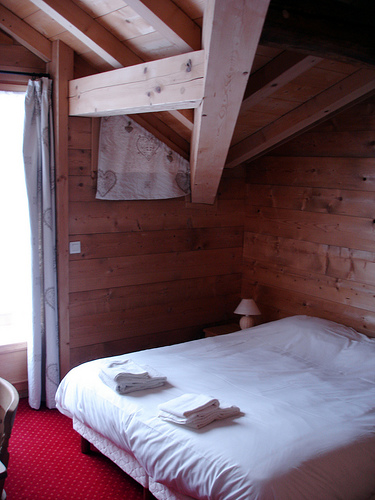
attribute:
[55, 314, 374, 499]
bed — white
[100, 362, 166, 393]
towels — white, piled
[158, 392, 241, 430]
towels — white, piled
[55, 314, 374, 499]
sheet — white, big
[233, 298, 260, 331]
lamp — small, yellow, bed side, white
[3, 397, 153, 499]
carpet — red, polk dot, gold, on floor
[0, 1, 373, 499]
room — under roof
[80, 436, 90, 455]
post — wooden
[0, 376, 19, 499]
chair — near desk, wooden, rounded, white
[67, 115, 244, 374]
wall — wood, wooden panel, knotty pine, wooden, most likely oak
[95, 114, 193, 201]
curtain — white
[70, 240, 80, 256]
light switch — small, white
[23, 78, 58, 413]
curtain — light gray, long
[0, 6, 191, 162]
rafter — exposed wood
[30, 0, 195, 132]
rafter — exposed wood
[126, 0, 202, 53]
rafter — exposed wood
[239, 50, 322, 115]
rafter — exposed wood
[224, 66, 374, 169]
rafter — exposed wood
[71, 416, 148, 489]
box spring — pulled together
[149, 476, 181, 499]
box spring — pulled together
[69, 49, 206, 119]
structure — of roof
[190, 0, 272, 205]
structure — of roof